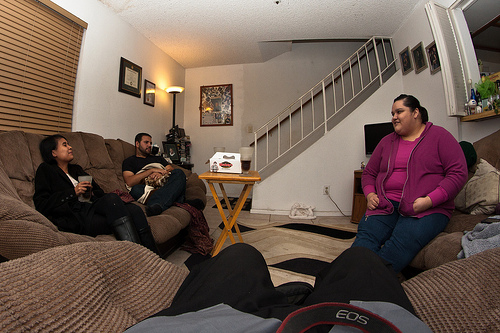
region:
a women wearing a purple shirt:
[314, 43, 499, 283]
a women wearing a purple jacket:
[304, 31, 499, 328]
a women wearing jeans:
[290, 77, 477, 314]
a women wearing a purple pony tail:
[362, 50, 486, 212]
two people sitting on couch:
[5, 89, 319, 272]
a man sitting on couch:
[114, 129, 183, 214]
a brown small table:
[194, 143, 294, 255]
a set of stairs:
[254, 71, 429, 201]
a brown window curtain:
[9, 2, 142, 136]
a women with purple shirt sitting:
[316, 60, 461, 272]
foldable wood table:
[203, 166, 265, 268]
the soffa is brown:
[8, 126, 234, 286]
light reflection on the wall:
[147, 53, 192, 108]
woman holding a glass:
[35, 141, 106, 218]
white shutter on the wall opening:
[427, 3, 480, 133]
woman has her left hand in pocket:
[405, 187, 448, 224]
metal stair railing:
[257, 39, 377, 212]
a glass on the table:
[230, 140, 262, 182]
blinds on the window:
[7, 8, 89, 145]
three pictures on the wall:
[399, 38, 450, 83]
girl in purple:
[357, 95, 456, 260]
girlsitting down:
[359, 94, 477, 266]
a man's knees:
[186, 249, 418, 328]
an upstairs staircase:
[250, 27, 409, 171]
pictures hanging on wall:
[116, 52, 182, 124]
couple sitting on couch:
[28, 129, 192, 233]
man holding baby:
[125, 127, 193, 236]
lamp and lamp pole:
[161, 79, 197, 134]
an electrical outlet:
[318, 182, 335, 200]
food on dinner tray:
[202, 144, 265, 248]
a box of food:
[156, 116, 298, 203]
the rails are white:
[237, 71, 374, 177]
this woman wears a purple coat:
[347, 90, 494, 217]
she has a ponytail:
[346, 69, 470, 201]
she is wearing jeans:
[331, 62, 496, 253]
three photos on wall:
[379, 27, 481, 86]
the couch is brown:
[48, 258, 140, 299]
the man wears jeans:
[100, 121, 236, 227]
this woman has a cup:
[26, 124, 148, 239]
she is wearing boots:
[15, 109, 167, 246]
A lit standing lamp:
[162, 80, 185, 133]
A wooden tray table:
[194, 160, 267, 255]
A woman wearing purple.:
[352, 92, 468, 292]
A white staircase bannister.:
[254, 29, 394, 177]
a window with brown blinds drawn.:
[0, 7, 92, 131]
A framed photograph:
[196, 79, 240, 128]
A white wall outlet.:
[319, 182, 335, 197]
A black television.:
[359, 117, 399, 156]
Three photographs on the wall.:
[390, 38, 443, 74]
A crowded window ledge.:
[457, 72, 499, 124]